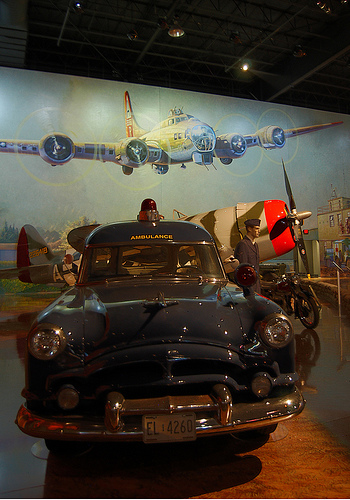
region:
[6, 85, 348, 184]
vintage airplane painted on wall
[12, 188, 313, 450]
old fashioned ambulance painted blue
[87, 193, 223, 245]
ambulance roof with red light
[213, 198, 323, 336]
male statue wearing uniform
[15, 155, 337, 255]
vintage airplane painted in camofluage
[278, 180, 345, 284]
building painted on wall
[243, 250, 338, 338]
old fashioned motorcycle on display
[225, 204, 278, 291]
male statue wearing uniform cap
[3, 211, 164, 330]
tree and grass painted on wall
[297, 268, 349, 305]
line of sandbags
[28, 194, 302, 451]
old model of ambulance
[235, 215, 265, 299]
mannequin in military uniform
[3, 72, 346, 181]
painting of airplane on wall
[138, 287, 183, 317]
hood ornament on dark automobile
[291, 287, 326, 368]
motorcycle wheel and shadow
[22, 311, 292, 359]
headlights on older model car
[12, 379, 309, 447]
bumper and license plate of car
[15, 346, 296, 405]
front grill of antique car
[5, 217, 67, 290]
airplane tailwing with call numbers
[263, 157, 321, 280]
front propellar of an airplane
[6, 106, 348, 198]
a model plane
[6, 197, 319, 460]
this is a car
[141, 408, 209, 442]
the number plate of a car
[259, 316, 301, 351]
this is the head lights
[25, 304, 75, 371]
this is the head lights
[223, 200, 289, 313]
this is a person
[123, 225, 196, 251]
a letter on the car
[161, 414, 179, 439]
a number on the car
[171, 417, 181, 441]
a number on the car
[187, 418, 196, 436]
a number on the car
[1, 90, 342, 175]
A painting of a plane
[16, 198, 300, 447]
An old style ambulance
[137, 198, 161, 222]
Red and silver light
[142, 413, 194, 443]
The license plate is white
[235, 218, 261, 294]
Statue in a uniform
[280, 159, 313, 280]
Propeller is black and silver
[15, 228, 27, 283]
Red paint on plane's tail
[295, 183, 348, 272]
Two buildings in the painting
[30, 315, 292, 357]
The headlights are off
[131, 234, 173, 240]
The text is yellow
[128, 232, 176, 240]
yellow ambulance sign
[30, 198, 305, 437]
old fashioned blue ambulance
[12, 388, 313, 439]
old fashioned silver bumper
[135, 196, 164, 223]
red and silver siren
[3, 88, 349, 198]
large propeller plane picture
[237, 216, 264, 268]
man wearing sailor uniform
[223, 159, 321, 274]
sailor in front of propeller plane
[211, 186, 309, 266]
green white and red propeller plane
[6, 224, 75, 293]
red and green plane tail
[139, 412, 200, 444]
white and black license plate